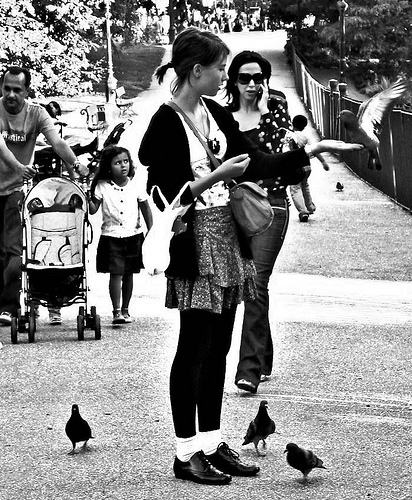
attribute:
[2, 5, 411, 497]
picture — black, white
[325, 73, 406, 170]
pigeon — flying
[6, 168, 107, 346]
stroller — light colored, empty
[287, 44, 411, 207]
fence — wrought iron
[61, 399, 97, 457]
pigeon — dark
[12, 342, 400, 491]
street — gray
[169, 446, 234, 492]
shoe — black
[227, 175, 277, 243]
bag — leather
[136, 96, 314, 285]
shirt — dark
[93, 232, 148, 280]
skirt — dark